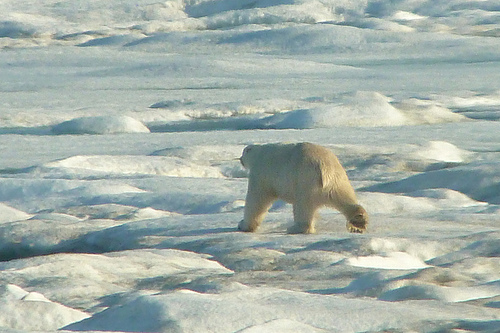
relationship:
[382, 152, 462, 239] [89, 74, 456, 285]
snow covered ground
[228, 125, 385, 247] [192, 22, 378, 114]
bear walking across snow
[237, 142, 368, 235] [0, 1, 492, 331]
bear walking across ice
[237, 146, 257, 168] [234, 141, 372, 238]
head of bear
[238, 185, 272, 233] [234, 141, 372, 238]
leg of bear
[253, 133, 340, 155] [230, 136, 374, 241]
back of bear